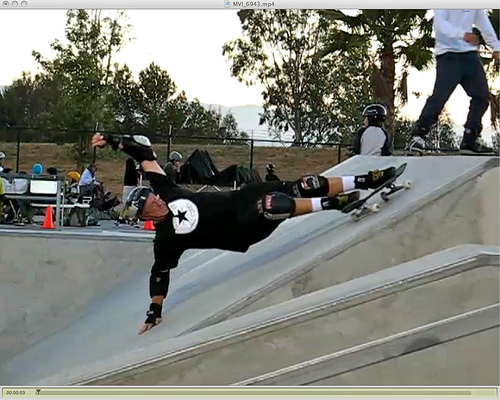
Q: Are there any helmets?
A: Yes, there is a helmet.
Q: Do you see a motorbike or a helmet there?
A: Yes, there is a helmet.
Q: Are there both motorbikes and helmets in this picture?
A: No, there is a helmet but no motorcycles.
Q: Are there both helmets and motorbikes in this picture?
A: No, there is a helmet but no motorcycles.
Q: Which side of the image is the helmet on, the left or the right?
A: The helmet is on the left of the image.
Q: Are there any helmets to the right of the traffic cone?
A: Yes, there is a helmet to the right of the traffic cone.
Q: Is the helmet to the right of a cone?
A: Yes, the helmet is to the right of a cone.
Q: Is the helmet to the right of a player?
A: No, the helmet is to the right of a cone.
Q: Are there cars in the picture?
A: No, there are no cars.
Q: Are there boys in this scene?
A: No, there are no boys.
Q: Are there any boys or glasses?
A: No, there are no boys or glasses.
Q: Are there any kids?
A: No, there are no kids.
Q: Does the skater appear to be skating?
A: Yes, the skater is skating.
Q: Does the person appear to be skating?
A: Yes, the skater is skating.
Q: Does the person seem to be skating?
A: Yes, the skater is skating.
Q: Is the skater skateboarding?
A: No, the skater is skating.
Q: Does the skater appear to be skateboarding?
A: No, the skater is skating.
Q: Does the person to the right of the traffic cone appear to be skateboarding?
A: No, the skater is skating.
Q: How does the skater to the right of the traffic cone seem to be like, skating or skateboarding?
A: The skater is skating.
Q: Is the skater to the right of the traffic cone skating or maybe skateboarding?
A: The skater is skating.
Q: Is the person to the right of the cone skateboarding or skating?
A: The skater is skating.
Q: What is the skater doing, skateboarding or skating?
A: The skater is skating.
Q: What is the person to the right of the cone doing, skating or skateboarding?
A: The skater is skating.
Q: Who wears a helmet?
A: The skater wears a helmet.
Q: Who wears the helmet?
A: The skater wears a helmet.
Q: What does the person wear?
A: The skater wears a helmet.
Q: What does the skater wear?
A: The skater wears a helmet.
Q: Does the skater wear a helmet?
A: Yes, the skater wears a helmet.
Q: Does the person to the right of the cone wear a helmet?
A: Yes, the skater wears a helmet.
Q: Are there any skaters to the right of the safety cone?
A: Yes, there is a skater to the right of the safety cone.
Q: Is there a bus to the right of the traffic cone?
A: No, there is a skater to the right of the traffic cone.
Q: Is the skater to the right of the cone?
A: Yes, the skater is to the right of the cone.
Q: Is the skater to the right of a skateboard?
A: No, the skater is to the right of the cone.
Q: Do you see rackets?
A: No, there are no rackets.